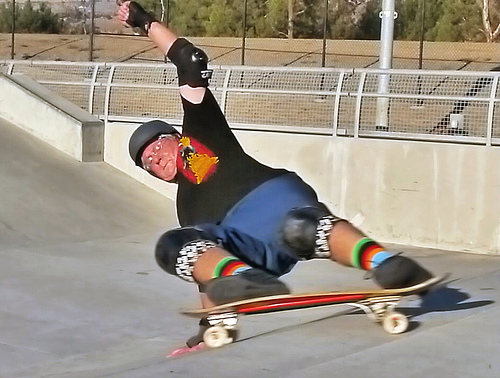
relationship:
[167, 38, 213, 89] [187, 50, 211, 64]
pad on elbow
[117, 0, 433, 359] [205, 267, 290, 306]
man wearing shoe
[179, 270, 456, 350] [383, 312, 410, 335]
board has wheel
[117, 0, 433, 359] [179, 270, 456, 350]
man on board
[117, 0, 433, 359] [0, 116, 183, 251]
man on ramp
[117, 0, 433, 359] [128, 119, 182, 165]
man wearing helmet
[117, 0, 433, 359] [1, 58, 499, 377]
man at park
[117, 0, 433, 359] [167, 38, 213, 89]
man wearing pad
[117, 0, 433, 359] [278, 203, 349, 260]
man wearing pad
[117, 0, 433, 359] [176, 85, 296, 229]
man wearing shirt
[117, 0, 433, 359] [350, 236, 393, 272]
man wearing sock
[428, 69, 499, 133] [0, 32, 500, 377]
shadow on ground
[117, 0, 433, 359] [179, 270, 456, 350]
man riding board